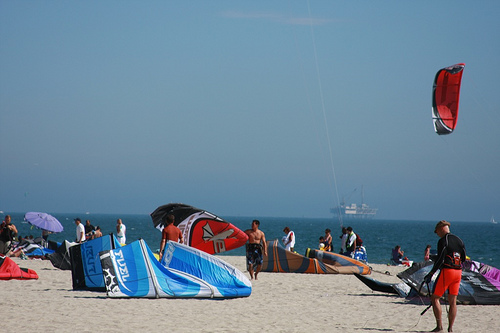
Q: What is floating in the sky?
A: Black, orange and white kite.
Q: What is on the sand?
A: Kites.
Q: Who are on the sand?
A: The people.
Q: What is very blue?
A: The water.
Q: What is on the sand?
A: A blue kite.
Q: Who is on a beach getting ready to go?
A: The windsurfers.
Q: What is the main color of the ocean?
A: Blue.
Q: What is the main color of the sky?
A: Blue.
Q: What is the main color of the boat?
A: White.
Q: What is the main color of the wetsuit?
A: Black.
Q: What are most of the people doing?
A: Flying kites.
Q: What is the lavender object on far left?
A: Umbrella.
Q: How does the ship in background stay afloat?
A: Water.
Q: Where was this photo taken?
A: Beach.